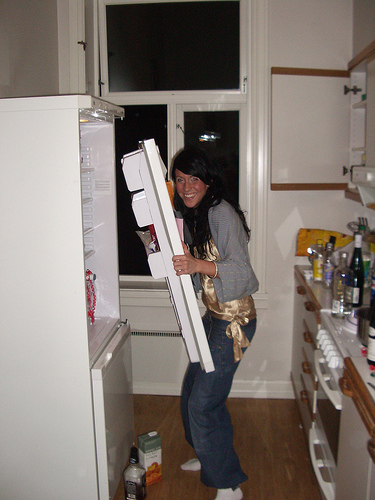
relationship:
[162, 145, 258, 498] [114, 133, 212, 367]
woman holding door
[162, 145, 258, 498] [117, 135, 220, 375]
woman holding door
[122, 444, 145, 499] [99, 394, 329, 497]
bottle on floor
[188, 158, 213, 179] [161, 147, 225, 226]
hair on woman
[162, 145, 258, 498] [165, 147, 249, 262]
woman has hair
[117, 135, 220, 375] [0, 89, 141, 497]
door off of refrigerator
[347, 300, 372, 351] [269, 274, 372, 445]
pot on stove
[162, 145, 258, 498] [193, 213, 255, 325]
woman wearing shirt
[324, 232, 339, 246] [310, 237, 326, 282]
top on bottle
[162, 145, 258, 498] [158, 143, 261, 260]
woman has hair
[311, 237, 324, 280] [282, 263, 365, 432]
bottle on top of cabinet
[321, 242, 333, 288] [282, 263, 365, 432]
bottle on top of cabinet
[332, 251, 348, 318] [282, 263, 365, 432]
bottle on top of cabinet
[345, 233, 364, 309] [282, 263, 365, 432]
bottle on top of cabinet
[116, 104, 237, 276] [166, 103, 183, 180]
window has panel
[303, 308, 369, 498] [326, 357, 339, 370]
cooker unit has knob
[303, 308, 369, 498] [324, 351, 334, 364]
cooker unit has knob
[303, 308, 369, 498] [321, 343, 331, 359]
cooker unit has knob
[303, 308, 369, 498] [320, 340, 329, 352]
cooker unit has knob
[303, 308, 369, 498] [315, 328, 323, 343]
cooker unit has knob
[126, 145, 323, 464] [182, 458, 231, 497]
girl wearing socks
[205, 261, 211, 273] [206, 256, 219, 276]
wrist wears bracelet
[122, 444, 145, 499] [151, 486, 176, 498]
bottle on floor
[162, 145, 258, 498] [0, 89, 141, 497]
woman in front of refrigerator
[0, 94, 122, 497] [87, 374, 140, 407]
refrigerator has door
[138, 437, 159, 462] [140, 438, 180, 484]
juice inside box